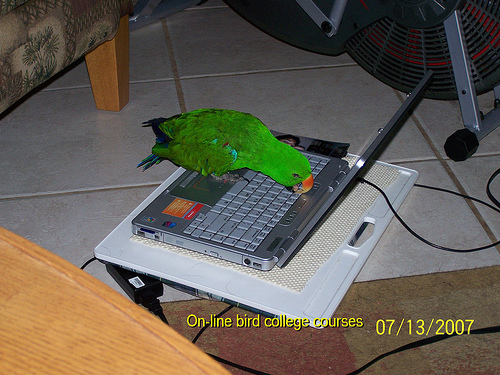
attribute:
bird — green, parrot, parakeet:
[135, 108, 316, 196]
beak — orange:
[288, 177, 317, 192]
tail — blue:
[142, 113, 187, 133]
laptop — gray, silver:
[133, 62, 429, 273]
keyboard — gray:
[194, 164, 291, 260]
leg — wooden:
[86, 22, 134, 115]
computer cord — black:
[360, 174, 498, 265]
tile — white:
[168, 18, 391, 154]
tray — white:
[98, 234, 379, 310]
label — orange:
[167, 198, 208, 225]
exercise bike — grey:
[227, 0, 499, 158]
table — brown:
[6, 251, 184, 373]